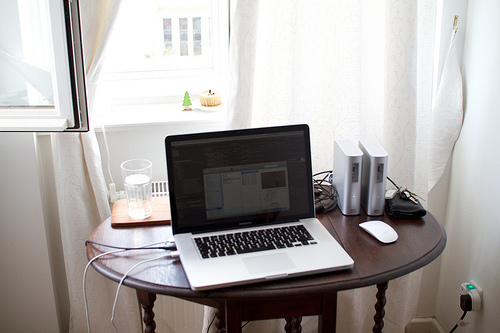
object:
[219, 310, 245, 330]
wooden leg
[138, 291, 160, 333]
wooden leg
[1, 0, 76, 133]
white frame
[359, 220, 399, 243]
magic mouse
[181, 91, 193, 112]
christmas tree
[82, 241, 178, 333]
cord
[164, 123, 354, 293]
computer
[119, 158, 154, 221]
glass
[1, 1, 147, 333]
curtain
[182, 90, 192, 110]
tree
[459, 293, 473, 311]
plug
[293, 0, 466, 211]
white curtain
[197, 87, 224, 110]
decoration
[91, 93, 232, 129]
window sill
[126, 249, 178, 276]
usb cord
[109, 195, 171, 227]
tray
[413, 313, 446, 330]
trim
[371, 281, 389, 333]
leg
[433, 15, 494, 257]
wall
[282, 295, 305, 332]
leg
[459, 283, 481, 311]
surge protector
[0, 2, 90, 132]
window frame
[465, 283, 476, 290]
light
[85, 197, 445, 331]
table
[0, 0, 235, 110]
window